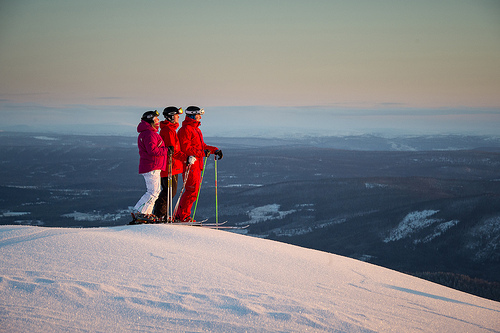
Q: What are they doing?
A: Skiing.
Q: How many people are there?
A: Three.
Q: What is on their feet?
A: Skiis.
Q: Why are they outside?
A: They are skiing.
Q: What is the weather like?
A: It is cold.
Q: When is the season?
A: Winter.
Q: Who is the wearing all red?
A: The person in front.